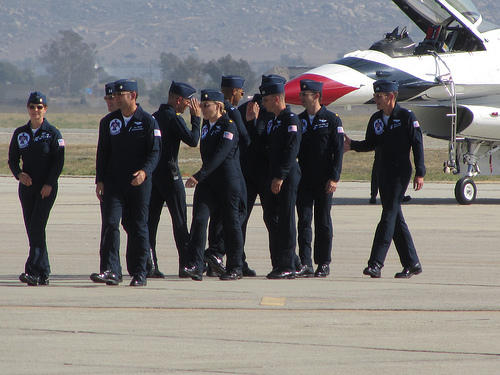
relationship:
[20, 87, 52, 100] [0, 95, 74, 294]
hat on person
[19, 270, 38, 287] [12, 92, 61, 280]
shoe on a woman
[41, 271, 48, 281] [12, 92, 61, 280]
shoe on a woman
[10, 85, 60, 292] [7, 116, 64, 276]
officer in uniform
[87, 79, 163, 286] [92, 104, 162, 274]
officer in uniform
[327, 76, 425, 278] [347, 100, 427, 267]
officer in uniform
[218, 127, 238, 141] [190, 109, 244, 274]
patch on uniform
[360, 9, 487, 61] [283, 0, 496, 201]
cockpit of jet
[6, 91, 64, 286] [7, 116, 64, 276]
officer in uniform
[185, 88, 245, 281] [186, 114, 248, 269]
person in uniform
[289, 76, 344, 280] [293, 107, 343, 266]
person in uniform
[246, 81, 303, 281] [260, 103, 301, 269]
person in uniform